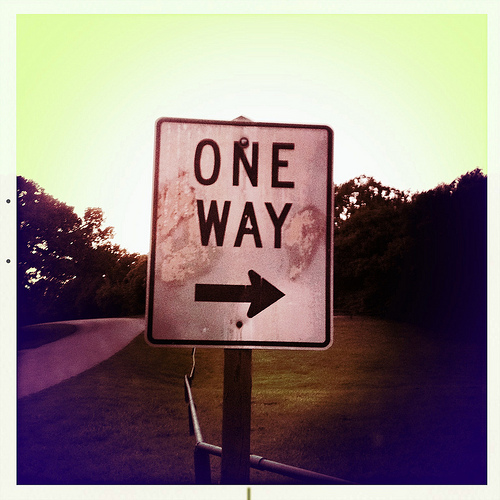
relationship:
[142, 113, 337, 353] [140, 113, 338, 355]
sign has edging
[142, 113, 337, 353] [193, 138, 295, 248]
sign says lettering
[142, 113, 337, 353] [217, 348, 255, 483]
sign on pole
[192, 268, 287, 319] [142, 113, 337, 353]
arrow on sign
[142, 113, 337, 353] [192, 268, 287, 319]
sign has arrow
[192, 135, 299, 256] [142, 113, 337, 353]
lettering on sign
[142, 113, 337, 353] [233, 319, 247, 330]
sign has bolt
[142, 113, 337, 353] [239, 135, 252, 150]
sign has bolt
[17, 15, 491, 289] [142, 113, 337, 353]
sky behind sign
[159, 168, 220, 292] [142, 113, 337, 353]
mark on sign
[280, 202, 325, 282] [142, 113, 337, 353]
mark on sign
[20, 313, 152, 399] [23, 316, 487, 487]
sidewalk in grass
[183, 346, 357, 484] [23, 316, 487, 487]
fence in grass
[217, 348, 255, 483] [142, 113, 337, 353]
pole holding sign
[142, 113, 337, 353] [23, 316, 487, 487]
sign near grass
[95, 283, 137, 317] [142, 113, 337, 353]
tree behind sign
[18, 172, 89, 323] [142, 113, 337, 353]
tree behind sign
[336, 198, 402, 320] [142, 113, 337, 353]
tree behind sign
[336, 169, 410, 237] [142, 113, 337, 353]
tree behind sign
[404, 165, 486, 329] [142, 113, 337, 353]
tree behind sign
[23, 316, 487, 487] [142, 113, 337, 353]
grass behind sign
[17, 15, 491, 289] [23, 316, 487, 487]
sky above grass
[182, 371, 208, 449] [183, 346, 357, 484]
railing on fence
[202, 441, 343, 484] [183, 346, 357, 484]
railing on fence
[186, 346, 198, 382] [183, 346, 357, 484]
railing on fence